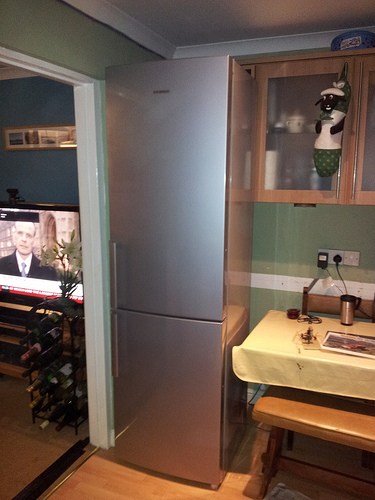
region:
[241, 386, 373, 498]
padded wooden bench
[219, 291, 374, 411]
yellow table cloth covers the table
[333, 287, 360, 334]
black and silver travel mug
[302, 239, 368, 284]
two outlets are being used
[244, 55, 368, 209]
wood and glass cupboard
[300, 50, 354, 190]
sheep oven mitt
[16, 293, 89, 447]
many different wine bottles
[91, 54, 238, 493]
tall stainless steel refridgerator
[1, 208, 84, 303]
television is on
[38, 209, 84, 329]
white flowers on the wine rack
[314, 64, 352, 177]
green and white cow bag hanging on the cupboard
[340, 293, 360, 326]
silver coffee cup with black handle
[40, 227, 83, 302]
white and green flowers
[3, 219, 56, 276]
man on TV in a suit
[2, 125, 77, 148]
framed photos on the wall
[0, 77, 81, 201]
section of blue wall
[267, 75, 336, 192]
clear cupboard door section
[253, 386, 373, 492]
wooden bench seat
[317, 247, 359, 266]
white wall outlet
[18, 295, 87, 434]
black wine rack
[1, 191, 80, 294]
a flat screen tv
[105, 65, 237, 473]
a silver refrigerator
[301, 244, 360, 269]
a electrical outlet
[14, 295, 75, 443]
a wine rack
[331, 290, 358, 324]
a silver thermas mug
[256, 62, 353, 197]
several dishes in a cabinet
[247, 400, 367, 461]
a bench seat with leather covering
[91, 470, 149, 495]
hardwood flooring in a kitchen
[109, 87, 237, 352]
a refrigerator with two doors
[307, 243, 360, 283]
two cords plugged into outlet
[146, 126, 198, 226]
stainless steel refrigerator in kitchen.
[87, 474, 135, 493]
wood on the kitchen floor.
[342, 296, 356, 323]
coffee mug on the table.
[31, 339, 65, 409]
wine bottles in living room.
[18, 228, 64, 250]
image on television screen.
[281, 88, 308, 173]
cupboard next to refrigerator.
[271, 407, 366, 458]
bench next to table.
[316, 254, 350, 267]
outlet on the wall.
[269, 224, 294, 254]
green paint on the wall.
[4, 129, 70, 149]
pictures on the wall.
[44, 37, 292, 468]
the fridge is grey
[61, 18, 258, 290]
the fridge is grey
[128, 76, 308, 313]
the fridge is grey